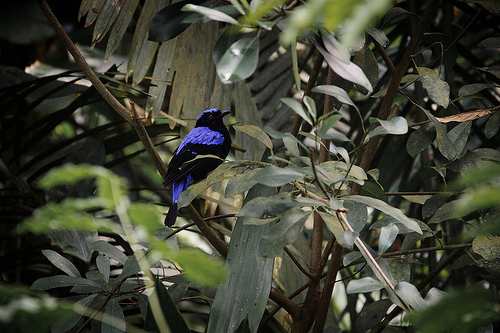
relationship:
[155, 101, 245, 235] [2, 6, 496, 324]
bird in a tree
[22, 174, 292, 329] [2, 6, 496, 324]
leaves on a tree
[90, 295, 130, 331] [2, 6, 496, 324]
leaf on a tree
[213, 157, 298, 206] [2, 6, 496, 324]
leaf on a tree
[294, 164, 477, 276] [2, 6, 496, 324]
leaves on a tree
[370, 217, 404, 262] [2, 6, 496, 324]
leaf on a tree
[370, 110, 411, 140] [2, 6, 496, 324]
leaf on a tree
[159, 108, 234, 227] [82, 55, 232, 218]
bird sitting on branch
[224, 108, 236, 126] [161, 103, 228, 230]
beak of bird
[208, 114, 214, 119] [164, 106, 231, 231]
eye of bird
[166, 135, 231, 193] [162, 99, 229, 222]
body of bird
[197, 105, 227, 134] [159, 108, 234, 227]
head of a bird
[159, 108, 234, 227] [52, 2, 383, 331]
bird perched on tree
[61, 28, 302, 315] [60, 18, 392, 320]
branch of tree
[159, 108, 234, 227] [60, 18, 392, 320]
bird perched on tree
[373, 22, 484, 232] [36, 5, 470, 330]
leaves of trees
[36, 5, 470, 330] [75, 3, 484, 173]
trees in background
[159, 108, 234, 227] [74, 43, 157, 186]
bird perched on branch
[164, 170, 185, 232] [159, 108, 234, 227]
tail of a bird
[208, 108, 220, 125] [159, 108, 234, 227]
eye of a bird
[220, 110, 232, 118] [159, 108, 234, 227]
beak of a bird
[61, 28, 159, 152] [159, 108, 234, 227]
branch with a bird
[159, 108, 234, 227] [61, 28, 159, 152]
bird on a branch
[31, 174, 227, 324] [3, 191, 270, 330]
leaves in foreground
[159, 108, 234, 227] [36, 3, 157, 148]
bird standing on a branch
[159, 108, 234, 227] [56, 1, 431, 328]
bird in a tree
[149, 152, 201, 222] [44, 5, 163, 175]
limb on a branch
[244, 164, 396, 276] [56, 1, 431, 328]
leaves on a tree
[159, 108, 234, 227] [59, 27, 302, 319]
bird sitting on branch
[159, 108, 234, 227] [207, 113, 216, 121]
bird has eye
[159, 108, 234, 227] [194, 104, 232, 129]
bird has head